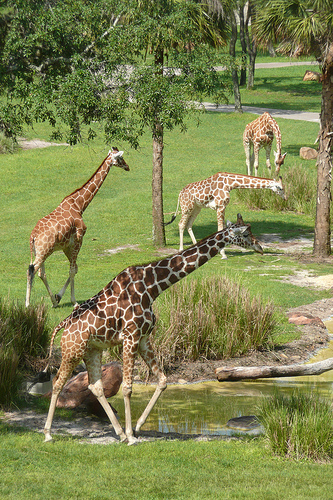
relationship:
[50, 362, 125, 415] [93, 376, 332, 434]
boulder by water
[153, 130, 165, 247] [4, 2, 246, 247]
trunk of tree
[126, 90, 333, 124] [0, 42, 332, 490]
pathway goes through grounds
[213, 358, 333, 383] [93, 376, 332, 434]
log lays in water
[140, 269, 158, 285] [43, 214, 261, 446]
spot on giraffe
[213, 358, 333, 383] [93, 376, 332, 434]
log laying across water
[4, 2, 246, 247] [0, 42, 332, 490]
tree in grounds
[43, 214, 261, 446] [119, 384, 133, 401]
giraffe has knee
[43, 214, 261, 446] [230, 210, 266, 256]
giraffe has head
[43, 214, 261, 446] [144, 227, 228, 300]
giraffe has neck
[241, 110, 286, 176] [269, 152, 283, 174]
giraffe bending head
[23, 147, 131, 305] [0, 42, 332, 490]
giraffe walking on grounds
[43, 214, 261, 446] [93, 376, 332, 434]
giraffe walking next to water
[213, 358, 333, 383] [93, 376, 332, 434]
log fallen next to water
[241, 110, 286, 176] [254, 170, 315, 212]
giraffe foraging for food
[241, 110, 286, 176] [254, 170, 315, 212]
giraffe searching for food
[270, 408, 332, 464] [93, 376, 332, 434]
grass bordering water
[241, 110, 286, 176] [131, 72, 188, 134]
giraffe eat leaves